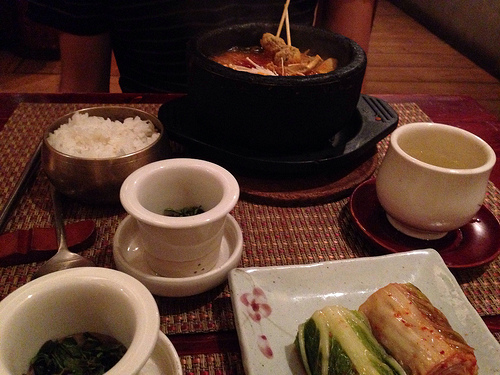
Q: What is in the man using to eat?
A: Chopsticks.